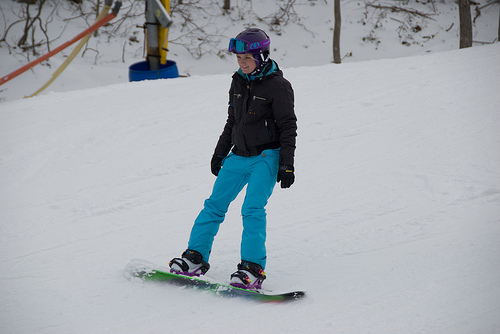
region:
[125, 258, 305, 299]
Mostly green colored snow board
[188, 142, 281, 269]
Blue snow pants on a girl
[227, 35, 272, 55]
Blue and purple goggles on a girl's head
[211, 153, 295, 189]
Black gloves on a girl skiing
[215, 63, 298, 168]
Black jacket on a girl snowboarding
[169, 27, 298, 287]
A girl on a snowboard with a purple helmet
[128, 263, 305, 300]
Mostly green snowboard a girl is on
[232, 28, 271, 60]
Dark helmet with goggles on the front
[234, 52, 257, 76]
White face of a girl snowboarding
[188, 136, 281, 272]
Blue pants on a girl snowboarding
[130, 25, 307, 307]
Woman standing on snow skis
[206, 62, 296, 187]
Dark blue snow jacket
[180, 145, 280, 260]
Light blue pants worn by young lady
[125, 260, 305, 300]
Ski board in the snow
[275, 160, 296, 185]
Black left glove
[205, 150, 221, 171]
Right black glove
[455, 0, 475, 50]
Trunk of tree in the snow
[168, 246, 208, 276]
Ski boot on right foot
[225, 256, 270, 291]
Left ski boot of young lady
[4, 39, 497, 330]
Snow covered hill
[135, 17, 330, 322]
Woman snowboarder stylish colors.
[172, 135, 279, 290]
Teal pants, purple white boots.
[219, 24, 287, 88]
Purple safety helmet teal goggles.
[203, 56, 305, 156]
Navy ski jacket teal hood.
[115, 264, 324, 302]
Snowboard underside bright green.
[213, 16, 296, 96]
Woman excited start slope run.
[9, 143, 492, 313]
Tracks snow busy ski slope.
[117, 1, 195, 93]
Ski lift equipment side slope.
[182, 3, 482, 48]
Sparse tree limbs fell ground.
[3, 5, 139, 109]
Safety orange red ropes.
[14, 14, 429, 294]
this child is skiing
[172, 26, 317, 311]
the girl is snow boarding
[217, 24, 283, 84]
she is wearing a purple helmet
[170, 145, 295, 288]
she has on light blue pants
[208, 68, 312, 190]
she is wearing a dark grey jacket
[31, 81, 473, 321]
snow is very smooth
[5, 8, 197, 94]
objects on the slope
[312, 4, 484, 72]
trees on the slope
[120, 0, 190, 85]
some type of item on the slope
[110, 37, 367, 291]
the girl is leaning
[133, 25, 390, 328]
a woman snowboarding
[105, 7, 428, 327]
a snowboarder stopping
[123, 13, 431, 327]
a woman wearing bright blue pants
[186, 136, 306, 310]
bright blue snowboard pants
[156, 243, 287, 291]
purple and grey snowboard boots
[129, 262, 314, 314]
a neon green snowboard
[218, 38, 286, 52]
purple and blue snowboard goggles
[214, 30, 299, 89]
her goggles are on her helmet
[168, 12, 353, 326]
she is snowboarding alone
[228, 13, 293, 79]
she has blonde hair covered by her helment